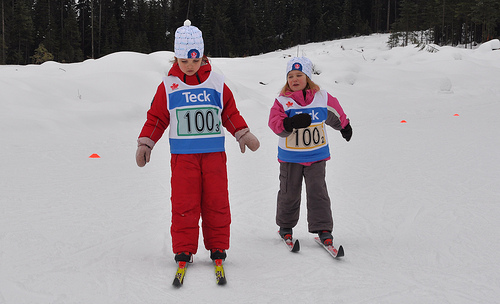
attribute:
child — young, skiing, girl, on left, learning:
[134, 19, 261, 262]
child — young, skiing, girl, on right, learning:
[267, 56, 353, 246]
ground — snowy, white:
[1, 29, 499, 304]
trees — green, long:
[1, 1, 499, 66]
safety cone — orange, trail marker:
[89, 153, 101, 159]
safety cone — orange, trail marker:
[399, 119, 407, 124]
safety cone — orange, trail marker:
[453, 112, 460, 117]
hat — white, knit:
[173, 19, 204, 60]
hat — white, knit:
[286, 55, 315, 81]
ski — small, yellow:
[172, 261, 186, 286]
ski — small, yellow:
[213, 259, 226, 285]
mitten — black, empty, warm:
[282, 113, 311, 132]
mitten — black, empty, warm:
[340, 124, 353, 141]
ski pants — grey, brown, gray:
[276, 160, 333, 234]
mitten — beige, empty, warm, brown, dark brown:
[136, 144, 152, 167]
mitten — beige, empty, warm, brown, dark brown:
[238, 131, 260, 154]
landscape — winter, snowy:
[0, 1, 499, 303]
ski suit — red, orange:
[137, 55, 249, 254]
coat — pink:
[269, 86, 349, 167]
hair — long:
[277, 74, 320, 97]